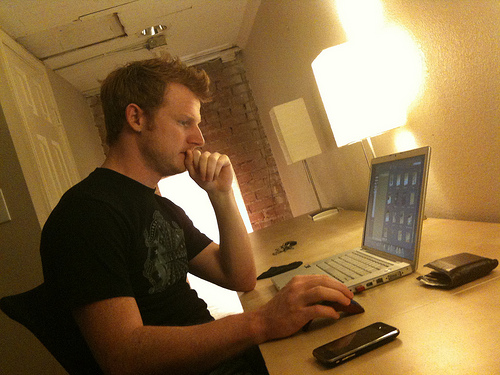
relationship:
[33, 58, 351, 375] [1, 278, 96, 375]
man in chair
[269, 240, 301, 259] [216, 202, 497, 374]
keys on table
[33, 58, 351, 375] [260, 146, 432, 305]
man uses laptop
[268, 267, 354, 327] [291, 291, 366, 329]
hand on mouse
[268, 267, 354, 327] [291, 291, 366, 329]
hand of mouse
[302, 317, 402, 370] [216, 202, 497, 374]
phone on table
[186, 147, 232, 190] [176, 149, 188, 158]
hand on mouth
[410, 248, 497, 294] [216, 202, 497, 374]
wallet on table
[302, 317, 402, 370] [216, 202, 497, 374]
cell phone on counter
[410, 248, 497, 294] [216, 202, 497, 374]
wallet on counter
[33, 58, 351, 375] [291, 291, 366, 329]
man uses mouse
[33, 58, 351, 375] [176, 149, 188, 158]
man touches mouth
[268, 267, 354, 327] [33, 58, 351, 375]
hand of man